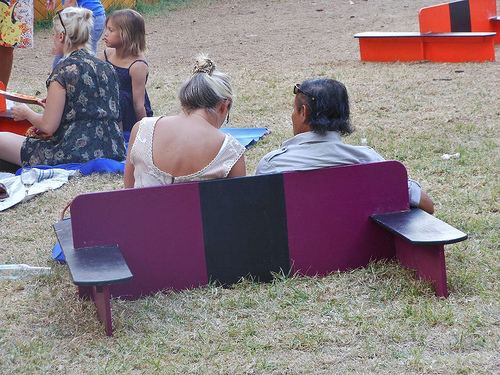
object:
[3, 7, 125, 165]
person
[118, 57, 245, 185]
person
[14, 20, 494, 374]
picnic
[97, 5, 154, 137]
girl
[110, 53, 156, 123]
dress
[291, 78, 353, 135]
head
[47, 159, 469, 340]
seat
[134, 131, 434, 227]
sitting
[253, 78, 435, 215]
man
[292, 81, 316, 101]
glasses